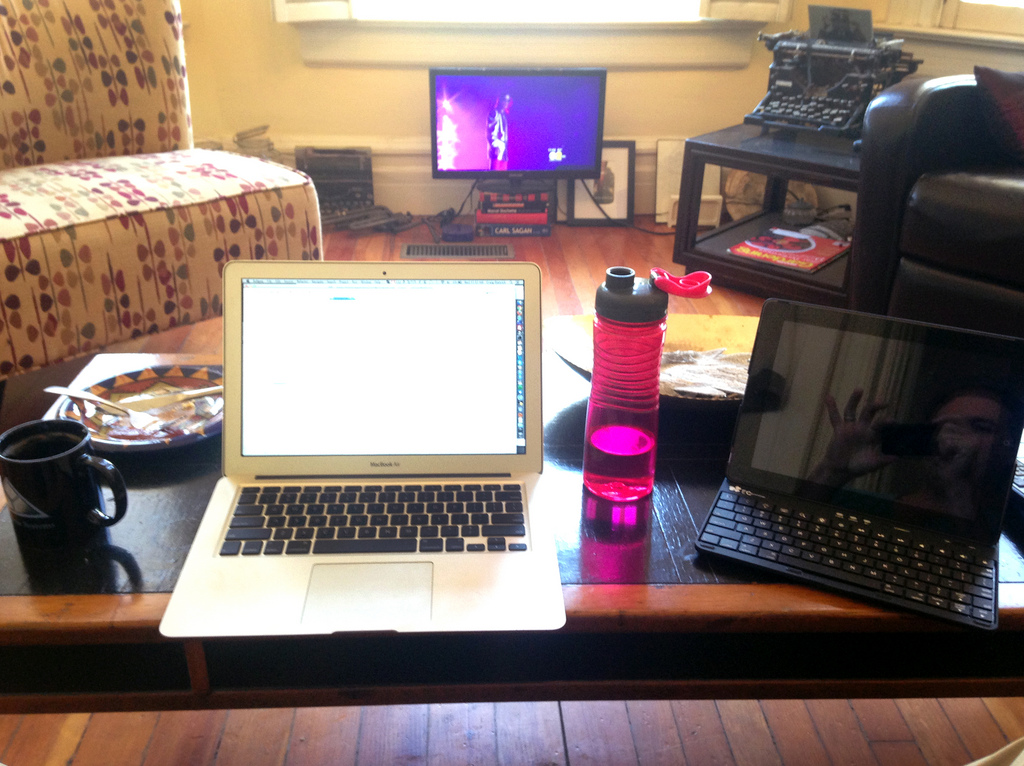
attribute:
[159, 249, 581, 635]
laptop — active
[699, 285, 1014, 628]
laptop — silver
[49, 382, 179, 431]
fork — silver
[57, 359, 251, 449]
plate — blue, yellow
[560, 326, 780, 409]
bowl — brown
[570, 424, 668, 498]
water — translucent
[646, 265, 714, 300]
cap — bottle cap, open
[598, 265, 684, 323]
lid — black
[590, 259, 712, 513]
bottle — pink, black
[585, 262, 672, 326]
top — black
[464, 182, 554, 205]
book — stacked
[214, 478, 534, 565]
keys — black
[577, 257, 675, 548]
bottle — water bottle, pink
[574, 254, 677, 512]
bottle — water bottle, pink, tall, black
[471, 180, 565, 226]
books — stacked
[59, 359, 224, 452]
plate — round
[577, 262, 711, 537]
water bottle — pink